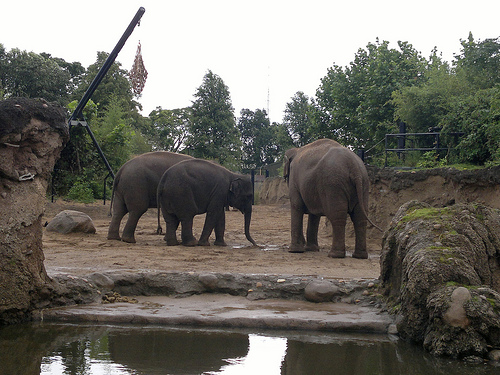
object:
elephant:
[283, 138, 383, 259]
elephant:
[157, 158, 258, 246]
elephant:
[107, 151, 221, 243]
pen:
[76, 225, 431, 285]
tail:
[155, 189, 163, 235]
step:
[35, 292, 392, 332]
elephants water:
[2, 319, 499, 374]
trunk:
[238, 205, 259, 245]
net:
[128, 43, 148, 99]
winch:
[71, 4, 143, 189]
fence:
[385, 122, 464, 170]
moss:
[395, 199, 485, 260]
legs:
[288, 190, 321, 253]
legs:
[198, 198, 227, 246]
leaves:
[333, 46, 429, 146]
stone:
[375, 196, 498, 372]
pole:
[67, 6, 145, 127]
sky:
[4, 4, 499, 67]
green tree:
[0, 38, 498, 162]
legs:
[107, 178, 148, 243]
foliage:
[3, 56, 115, 141]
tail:
[351, 171, 384, 232]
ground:
[65, 217, 445, 316]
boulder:
[45, 210, 96, 234]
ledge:
[368, 157, 498, 188]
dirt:
[382, 223, 433, 313]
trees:
[320, 40, 498, 160]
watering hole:
[236, 242, 290, 251]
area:
[64, 151, 402, 278]